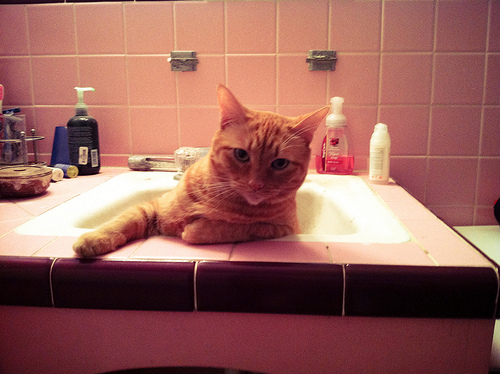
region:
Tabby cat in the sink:
[31, 76, 409, 303]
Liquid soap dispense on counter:
[61, 81, 107, 176]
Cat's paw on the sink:
[66, 216, 140, 265]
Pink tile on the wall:
[394, 19, 498, 177]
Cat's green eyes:
[223, 147, 299, 172]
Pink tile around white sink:
[0, 190, 478, 253]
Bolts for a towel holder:
[157, 45, 343, 74]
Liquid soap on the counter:
[317, 93, 351, 179]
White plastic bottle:
[363, 119, 394, 190]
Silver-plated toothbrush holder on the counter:
[0, 99, 45, 162]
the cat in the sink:
[72, 84, 317, 264]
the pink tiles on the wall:
[75, 9, 169, 84]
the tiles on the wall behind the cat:
[205, 13, 299, 81]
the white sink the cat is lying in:
[22, 157, 413, 243]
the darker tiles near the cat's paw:
[12, 255, 457, 306]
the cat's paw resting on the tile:
[65, 225, 120, 261]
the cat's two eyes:
[230, 142, 295, 168]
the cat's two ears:
[210, 81, 330, 139]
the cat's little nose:
[245, 177, 264, 188]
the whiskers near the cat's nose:
[175, 167, 318, 224]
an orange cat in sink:
[12, 11, 365, 300]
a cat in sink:
[54, 53, 494, 367]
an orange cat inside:
[126, 80, 390, 348]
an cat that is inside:
[83, 67, 424, 344]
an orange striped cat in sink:
[105, 68, 377, 296]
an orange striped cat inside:
[72, 10, 401, 299]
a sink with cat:
[62, 81, 474, 281]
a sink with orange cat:
[123, 60, 463, 297]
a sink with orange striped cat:
[144, 77, 485, 360]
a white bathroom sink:
[50, 24, 342, 361]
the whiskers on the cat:
[188, 171, 326, 228]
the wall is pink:
[197, 15, 474, 151]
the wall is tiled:
[106, 15, 418, 89]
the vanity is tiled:
[5, 191, 494, 320]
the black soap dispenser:
[53, 75, 128, 180]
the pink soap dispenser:
[319, 85, 367, 182]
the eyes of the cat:
[228, 139, 310, 176]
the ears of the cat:
[209, 75, 328, 149]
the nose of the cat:
[246, 176, 267, 193]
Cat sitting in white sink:
[70, 80, 331, 260]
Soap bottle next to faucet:
[310, 90, 355, 175]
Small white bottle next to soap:
[365, 116, 395, 183]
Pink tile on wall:
[377, 102, 430, 156]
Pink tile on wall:
[225, 51, 276, 104]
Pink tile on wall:
[74, 53, 129, 102]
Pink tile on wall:
[128, 105, 180, 157]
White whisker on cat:
[193, 162, 239, 185]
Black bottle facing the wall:
[66, 83, 108, 175]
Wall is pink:
[0, 0, 498, 224]